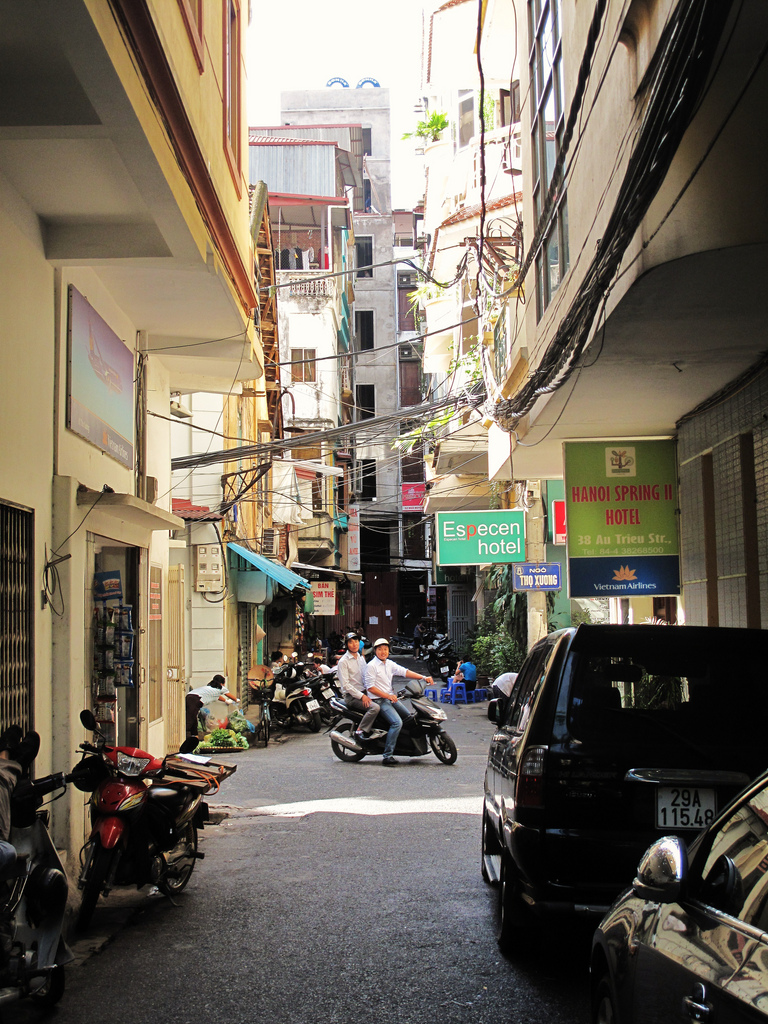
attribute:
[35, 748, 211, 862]
motorbike — red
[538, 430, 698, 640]
sign — Hanoit Spring II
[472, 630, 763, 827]
van — dark colored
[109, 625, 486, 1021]
street — red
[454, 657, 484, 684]
shirt — blue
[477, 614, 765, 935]
van — black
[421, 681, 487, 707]
chairs — blue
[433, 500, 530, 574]
sign — green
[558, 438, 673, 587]
sign — hotel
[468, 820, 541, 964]
tires — black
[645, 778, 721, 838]
plate — license